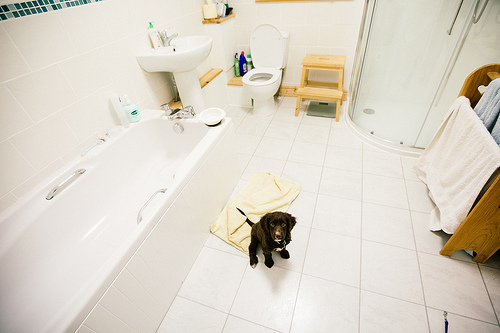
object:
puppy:
[236, 207, 297, 268]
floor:
[157, 97, 499, 333]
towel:
[209, 172, 301, 255]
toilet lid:
[250, 23, 285, 69]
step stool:
[294, 53, 345, 123]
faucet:
[164, 106, 196, 121]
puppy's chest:
[271, 239, 287, 251]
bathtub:
[0, 107, 263, 333]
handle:
[44, 167, 87, 200]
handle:
[136, 189, 168, 225]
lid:
[148, 21, 153, 28]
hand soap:
[148, 20, 161, 49]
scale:
[305, 101, 336, 118]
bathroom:
[0, 0, 500, 333]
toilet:
[241, 22, 290, 118]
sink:
[137, 37, 213, 72]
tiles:
[23, 8, 31, 15]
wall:
[0, 1, 187, 210]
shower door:
[346, 0, 500, 152]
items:
[239, 50, 247, 77]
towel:
[412, 95, 499, 234]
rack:
[435, 62, 500, 265]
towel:
[472, 77, 499, 130]